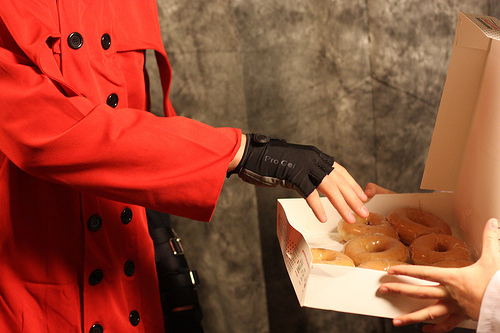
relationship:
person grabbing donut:
[0, 0, 370, 333] [330, 176, 377, 326]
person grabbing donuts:
[0, 0, 370, 333] [336, 211, 396, 243]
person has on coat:
[0, 0, 370, 333] [22, 10, 262, 331]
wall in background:
[162, 0, 471, 180] [235, 50, 318, 132]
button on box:
[96, 26, 118, 52] [57, 7, 158, 330]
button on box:
[67, 27, 86, 52] [57, 7, 158, 330]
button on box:
[114, 204, 136, 224] [57, 7, 158, 330]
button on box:
[81, 212, 113, 232] [57, 7, 158, 330]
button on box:
[84, 262, 106, 291] [57, 7, 158, 330]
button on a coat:
[113, 203, 132, 226] [3, 2, 242, 332]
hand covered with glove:
[373, 218, 499, 330] [234, 126, 340, 194]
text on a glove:
[258, 150, 301, 174] [230, 127, 338, 199]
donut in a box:
[342, 229, 412, 264] [274, 10, 484, 314]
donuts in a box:
[332, 202, 461, 272] [274, 10, 484, 314]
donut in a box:
[335, 213, 395, 243] [274, 10, 484, 314]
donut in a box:
[385, 207, 452, 246] [274, 10, 484, 314]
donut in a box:
[409, 232, 469, 267] [274, 10, 484, 314]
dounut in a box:
[342, 233, 409, 262] [274, 10, 484, 314]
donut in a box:
[309, 249, 355, 269] [274, 10, 484, 314]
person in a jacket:
[0, 8, 388, 323] [1, 5, 245, 331]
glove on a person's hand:
[233, 132, 327, 204] [296, 157, 380, 233]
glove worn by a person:
[226, 133, 335, 199] [0, 8, 388, 323]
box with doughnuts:
[274, 10, 484, 314] [339, 224, 418, 275]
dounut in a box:
[339, 228, 409, 269] [274, 10, 484, 314]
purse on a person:
[120, 189, 249, 330] [0, 0, 370, 333]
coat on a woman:
[3, 2, 242, 332] [0, 1, 375, 331]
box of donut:
[274, 10, 484, 314] [385, 207, 452, 246]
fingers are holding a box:
[372, 261, 469, 329] [256, 216, 358, 306]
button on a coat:
[62, 26, 86, 52] [3, 2, 242, 332]